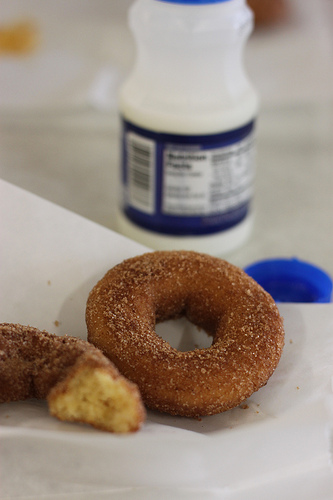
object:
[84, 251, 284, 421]
donut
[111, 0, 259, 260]
bottle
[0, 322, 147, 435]
donut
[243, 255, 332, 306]
cap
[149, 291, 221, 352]
hole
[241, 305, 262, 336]
sprinkles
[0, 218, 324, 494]
napkin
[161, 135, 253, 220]
nutrition facts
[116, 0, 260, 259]
milk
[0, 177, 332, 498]
box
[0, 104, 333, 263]
counter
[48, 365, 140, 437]
yellow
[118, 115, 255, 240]
label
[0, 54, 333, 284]
table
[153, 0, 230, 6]
blue top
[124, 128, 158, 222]
price code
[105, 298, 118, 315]
sugar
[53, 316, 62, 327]
crumbs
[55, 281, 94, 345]
shadow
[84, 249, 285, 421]
brown crust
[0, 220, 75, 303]
surface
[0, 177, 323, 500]
waxpaper